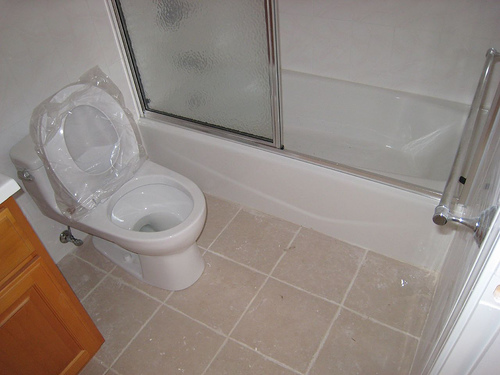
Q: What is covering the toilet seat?
A: Plastic.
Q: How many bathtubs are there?
A: One.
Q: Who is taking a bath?
A: No one.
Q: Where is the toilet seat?
A: Raised up.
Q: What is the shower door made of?
A: Glass.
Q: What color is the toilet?
A: White.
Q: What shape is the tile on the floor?
A: Square.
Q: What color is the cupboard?
A: Brown.